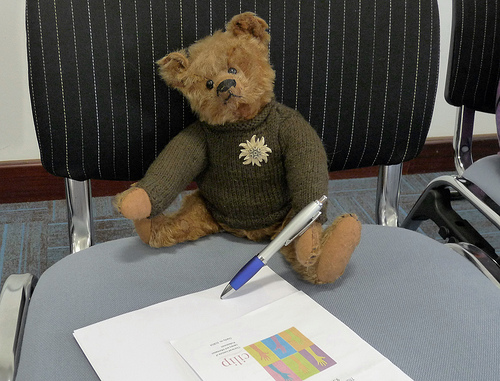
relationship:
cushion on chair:
[10, 211, 498, 379] [0, 0, 499, 380]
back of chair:
[25, 1, 435, 183] [0, 0, 499, 380]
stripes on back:
[25, 1, 432, 176] [25, 1, 435, 183]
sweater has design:
[142, 100, 332, 227] [235, 132, 275, 165]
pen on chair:
[219, 192, 328, 299] [0, 0, 499, 380]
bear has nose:
[109, 11, 363, 286] [214, 77, 236, 95]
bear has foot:
[126, 32, 413, 293] [311, 211, 361, 289]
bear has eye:
[109, 11, 363, 286] [198, 72, 219, 92]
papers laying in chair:
[76, 262, 398, 379] [21, 0, 427, 258]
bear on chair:
[109, 11, 363, 286] [0, 0, 499, 380]